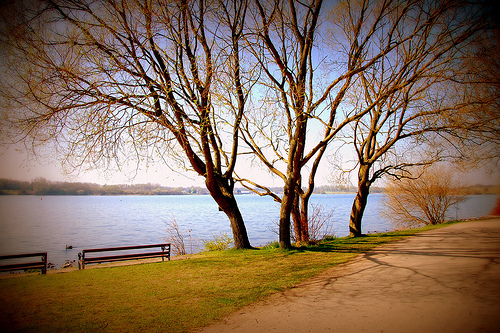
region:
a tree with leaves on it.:
[7, 0, 269, 258]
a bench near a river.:
[67, 228, 186, 275]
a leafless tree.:
[371, 114, 491, 235]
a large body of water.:
[0, 190, 492, 270]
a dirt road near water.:
[225, 216, 495, 332]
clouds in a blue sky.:
[0, 93, 394, 181]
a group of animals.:
[49, 233, 81, 269]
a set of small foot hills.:
[0, 177, 204, 194]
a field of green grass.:
[0, 225, 410, 330]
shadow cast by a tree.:
[346, 230, 421, 280]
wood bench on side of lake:
[75, 245, 172, 262]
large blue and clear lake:
[0, 190, 496, 271]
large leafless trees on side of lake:
[0, 6, 491, 244]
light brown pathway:
[200, 213, 496, 328]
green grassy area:
[8, 215, 459, 328]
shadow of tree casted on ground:
[293, 230, 493, 308]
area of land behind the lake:
[0, 175, 491, 195]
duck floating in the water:
[60, 241, 75, 251]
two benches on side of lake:
[0, 240, 171, 275]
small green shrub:
[201, 235, 233, 252]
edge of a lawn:
[202, 286, 220, 313]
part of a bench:
[126, 251, 138, 255]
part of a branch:
[471, 94, 475, 101]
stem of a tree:
[282, 190, 299, 215]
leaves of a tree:
[182, 102, 217, 147]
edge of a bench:
[103, 244, 107, 249]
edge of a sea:
[88, 191, 102, 202]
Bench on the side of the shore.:
[51, 206, 168, 319]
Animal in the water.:
[43, 223, 96, 330]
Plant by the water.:
[132, 160, 288, 279]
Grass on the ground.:
[186, 202, 308, 319]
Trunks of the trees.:
[153, 123, 419, 285]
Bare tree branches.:
[60, 52, 343, 189]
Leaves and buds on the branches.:
[8, 53, 170, 148]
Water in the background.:
[103, 160, 424, 329]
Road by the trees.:
[371, 195, 494, 307]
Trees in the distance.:
[25, 149, 199, 210]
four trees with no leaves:
[44, 6, 478, 236]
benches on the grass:
[0, 241, 177, 284]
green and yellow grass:
[15, 236, 384, 324]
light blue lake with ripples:
[10, 193, 490, 259]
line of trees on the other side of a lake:
[0, 171, 405, 191]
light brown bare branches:
[23, 50, 149, 163]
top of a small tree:
[367, 150, 460, 230]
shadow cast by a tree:
[355, 246, 460, 313]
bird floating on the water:
[60, 241, 73, 251]